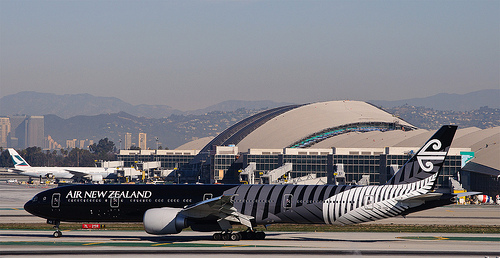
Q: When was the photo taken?
A: Daytime.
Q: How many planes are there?
A: Two.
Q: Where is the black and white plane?
A: Runway.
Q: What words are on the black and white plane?
A: Air New Zealand.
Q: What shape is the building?
A: Rounded.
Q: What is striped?
A: Plane.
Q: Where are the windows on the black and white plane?
A: Down the side.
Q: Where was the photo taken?
A: At an airport.